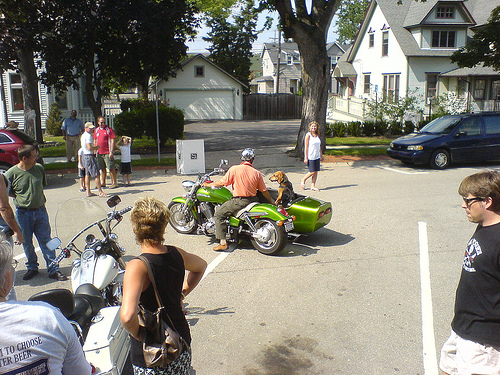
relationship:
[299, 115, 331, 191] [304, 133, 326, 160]
woman wearing tank top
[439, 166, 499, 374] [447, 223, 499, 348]
man wearing shirt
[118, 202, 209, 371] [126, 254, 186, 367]
woman has purse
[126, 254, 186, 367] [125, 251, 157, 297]
purse over shoulder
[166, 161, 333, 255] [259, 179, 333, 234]
motorcyle has side car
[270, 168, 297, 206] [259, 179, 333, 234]
dog in side car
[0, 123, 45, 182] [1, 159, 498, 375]
car on street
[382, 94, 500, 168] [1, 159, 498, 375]
van on street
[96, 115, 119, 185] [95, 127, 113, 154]
man wearing shirt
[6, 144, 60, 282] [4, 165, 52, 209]
man wearing shirt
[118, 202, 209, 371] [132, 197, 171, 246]
woman has hair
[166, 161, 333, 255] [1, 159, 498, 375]
motorcyle on street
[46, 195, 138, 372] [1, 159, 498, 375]
motorcyle on street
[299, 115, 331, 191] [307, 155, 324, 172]
woman wearing shorts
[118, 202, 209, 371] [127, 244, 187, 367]
woman wearing top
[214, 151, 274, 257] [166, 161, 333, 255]
man on motorcyle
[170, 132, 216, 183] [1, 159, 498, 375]
box on street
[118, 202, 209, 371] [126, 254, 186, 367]
woman carrying purse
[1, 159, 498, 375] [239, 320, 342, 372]
street has spot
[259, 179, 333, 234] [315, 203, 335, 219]
side car has lights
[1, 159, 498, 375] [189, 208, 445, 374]
street has stripes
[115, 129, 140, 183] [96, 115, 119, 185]
kid next to man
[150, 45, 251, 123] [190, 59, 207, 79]
garage has window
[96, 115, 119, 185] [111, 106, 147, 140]
man near bush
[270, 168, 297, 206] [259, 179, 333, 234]
dog sitting in side car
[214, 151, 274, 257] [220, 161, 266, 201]
man wearing shirt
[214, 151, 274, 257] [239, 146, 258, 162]
man wearing helmet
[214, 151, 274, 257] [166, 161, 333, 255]
man on top of motorcyle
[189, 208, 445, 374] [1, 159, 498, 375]
stripes on street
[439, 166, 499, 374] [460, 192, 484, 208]
man wearing sunglasses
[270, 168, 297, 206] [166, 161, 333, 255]
dog in motorcyle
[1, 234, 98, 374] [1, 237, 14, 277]
person has hair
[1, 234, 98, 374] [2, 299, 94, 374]
person wearing shirt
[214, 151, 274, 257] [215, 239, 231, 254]
man wearing shoes